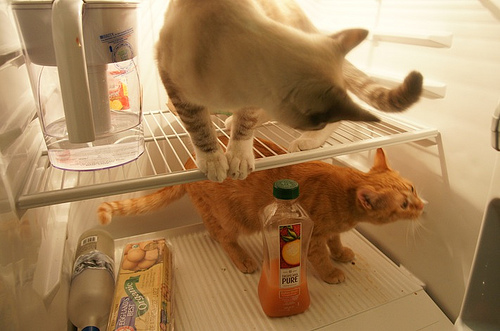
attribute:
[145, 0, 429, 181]
cat — tan, white, grey, playing, gray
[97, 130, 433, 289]
cat — auburn, orange, playing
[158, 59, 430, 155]
stripes — beige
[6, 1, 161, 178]
pitcher — white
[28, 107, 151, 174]
water — clean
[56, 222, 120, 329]
bottle — down, laying down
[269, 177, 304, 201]
lid — green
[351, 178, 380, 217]
ear — orange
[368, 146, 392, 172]
ear — orange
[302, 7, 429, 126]
tail — grey, brown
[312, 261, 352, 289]
paw — orange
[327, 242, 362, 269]
paw — orange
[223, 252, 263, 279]
paw — orange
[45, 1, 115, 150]
handle — white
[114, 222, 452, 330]
shelf — white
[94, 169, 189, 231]
tail — orange, white